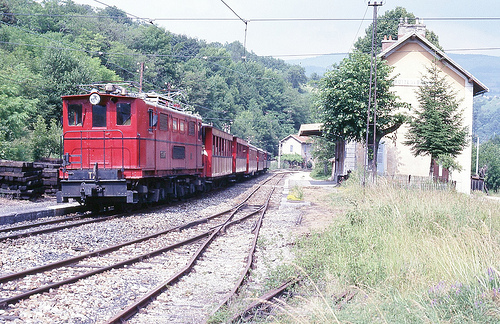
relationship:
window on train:
[109, 93, 139, 127] [43, 104, 289, 234]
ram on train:
[57, 169, 129, 204] [52, 92, 272, 199]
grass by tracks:
[285, 175, 500, 321] [25, 195, 275, 324]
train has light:
[53, 82, 273, 212] [82, 85, 105, 104]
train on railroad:
[53, 82, 273, 212] [10, 148, 293, 321]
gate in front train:
[66, 131, 143, 178] [53, 82, 273, 212]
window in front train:
[109, 93, 139, 127] [53, 82, 273, 212]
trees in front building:
[314, 45, 410, 175] [359, 20, 487, 191]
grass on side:
[334, 175, 498, 321] [392, 175, 484, 321]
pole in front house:
[359, 9, 394, 178] [296, 15, 495, 230]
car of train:
[52, 80, 207, 212] [53, 82, 273, 212]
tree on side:
[413, 61, 465, 185] [390, 132, 413, 176]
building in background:
[280, 135, 334, 167] [234, 37, 314, 224]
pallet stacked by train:
[0, 152, 43, 199] [53, 82, 273, 212]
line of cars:
[57, 95, 208, 209] [205, 120, 238, 176]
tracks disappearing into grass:
[173, 222, 305, 294] [281, 168, 310, 201]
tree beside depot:
[413, 61, 465, 185] [271, 17, 491, 193]